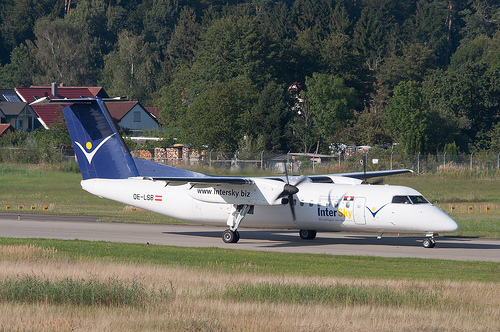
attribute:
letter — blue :
[243, 190, 251, 200]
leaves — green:
[416, 76, 461, 129]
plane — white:
[54, 92, 478, 274]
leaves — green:
[225, 95, 265, 129]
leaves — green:
[143, 38, 194, 88]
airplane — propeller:
[47, 95, 459, 249]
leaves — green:
[348, 20, 480, 131]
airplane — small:
[34, 83, 460, 248]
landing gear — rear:
[217, 211, 248, 245]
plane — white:
[51, 82, 469, 266]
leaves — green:
[192, 27, 266, 80]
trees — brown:
[1, 6, 496, 158]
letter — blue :
[314, 204, 326, 221]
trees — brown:
[241, 10, 499, 158]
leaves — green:
[332, 46, 363, 88]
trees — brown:
[329, 12, 488, 160]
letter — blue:
[315, 199, 326, 223]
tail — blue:
[26, 87, 140, 177]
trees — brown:
[298, 3, 484, 151]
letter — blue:
[194, 184, 202, 196]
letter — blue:
[200, 187, 208, 197]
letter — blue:
[239, 189, 245, 202]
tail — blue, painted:
[23, 90, 144, 179]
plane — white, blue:
[48, 90, 459, 248]